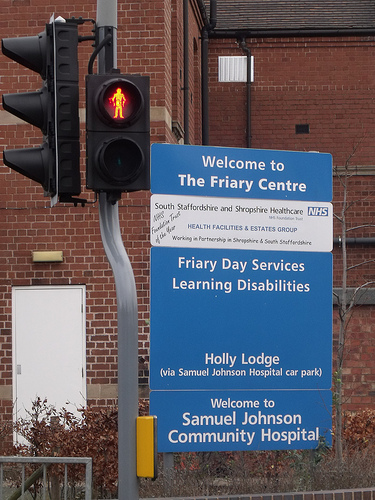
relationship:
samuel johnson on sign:
[179, 412, 306, 427] [146, 144, 340, 461]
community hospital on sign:
[163, 426, 323, 449] [146, 144, 340, 461]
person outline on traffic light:
[109, 85, 130, 119] [88, 69, 149, 190]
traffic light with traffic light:
[88, 69, 149, 190] [8, 9, 83, 209]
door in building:
[11, 284, 86, 444] [2, 3, 373, 460]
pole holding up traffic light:
[94, 189, 147, 499] [88, 69, 149, 190]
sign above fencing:
[146, 144, 340, 461] [4, 454, 371, 499]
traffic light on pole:
[88, 69, 149, 190] [94, 189, 147, 499]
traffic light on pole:
[8, 9, 83, 209] [94, 189, 147, 499]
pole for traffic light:
[94, 189, 147, 499] [88, 69, 149, 190]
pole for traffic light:
[94, 189, 147, 499] [8, 9, 83, 209]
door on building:
[11, 284, 86, 444] [2, 3, 373, 460]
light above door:
[32, 248, 65, 264] [11, 284, 86, 444]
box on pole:
[135, 413, 162, 486] [94, 189, 147, 499]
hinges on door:
[80, 301, 88, 381] [11, 284, 86, 444]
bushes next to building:
[19, 392, 370, 500] [2, 3, 373, 460]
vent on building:
[216, 56, 255, 84] [2, 3, 373, 460]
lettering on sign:
[159, 146, 323, 446] [146, 144, 340, 461]